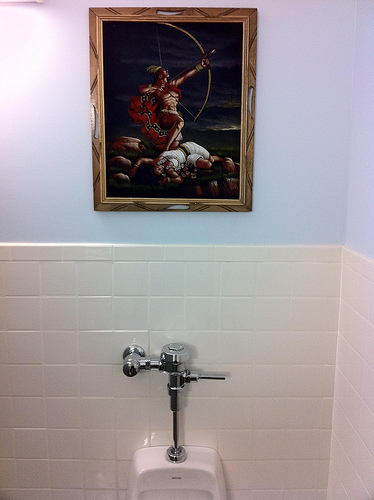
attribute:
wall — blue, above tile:
[260, 16, 363, 229]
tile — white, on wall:
[5, 250, 105, 442]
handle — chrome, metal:
[181, 372, 225, 386]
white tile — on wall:
[4, 242, 265, 325]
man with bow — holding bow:
[132, 25, 217, 144]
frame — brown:
[91, 8, 107, 213]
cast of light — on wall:
[5, 1, 52, 157]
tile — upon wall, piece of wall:
[111, 265, 145, 299]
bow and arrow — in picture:
[153, 25, 218, 117]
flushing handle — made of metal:
[184, 372, 199, 385]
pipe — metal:
[120, 347, 145, 376]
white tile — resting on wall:
[81, 295, 115, 335]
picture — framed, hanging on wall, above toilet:
[87, 7, 253, 210]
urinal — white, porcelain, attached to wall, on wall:
[116, 345, 230, 498]